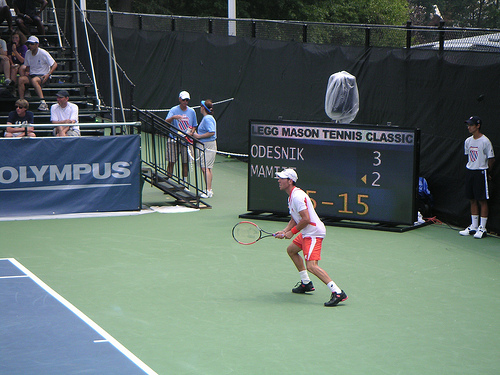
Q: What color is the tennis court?
A: Green and blue.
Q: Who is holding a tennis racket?
A: The man in red shorts.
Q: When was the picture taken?
A: Daytime.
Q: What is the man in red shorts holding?
A: A tennis racket.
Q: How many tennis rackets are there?
A: One.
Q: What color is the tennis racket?
A: Black and red.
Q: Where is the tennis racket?
A: In the hands of the man in red shorts.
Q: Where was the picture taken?
A: At a tennis match.